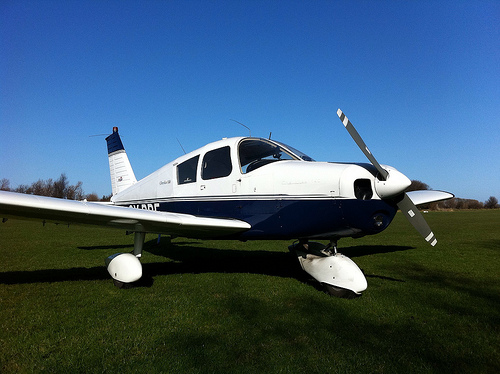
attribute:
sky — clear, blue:
[53, 7, 480, 86]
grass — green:
[174, 295, 259, 349]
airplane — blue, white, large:
[44, 109, 468, 301]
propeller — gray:
[331, 107, 460, 254]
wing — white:
[20, 191, 234, 242]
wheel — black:
[112, 279, 140, 293]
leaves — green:
[45, 181, 69, 190]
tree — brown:
[484, 191, 498, 211]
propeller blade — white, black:
[333, 106, 375, 163]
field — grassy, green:
[462, 235, 493, 300]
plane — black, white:
[75, 117, 411, 261]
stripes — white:
[225, 191, 347, 201]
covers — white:
[108, 256, 142, 276]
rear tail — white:
[105, 158, 130, 180]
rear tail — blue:
[107, 134, 122, 152]